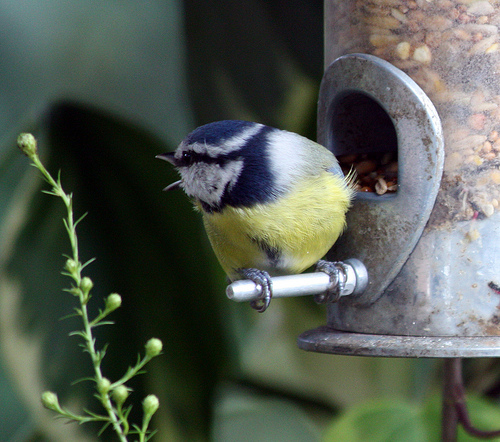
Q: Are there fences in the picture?
A: No, there are no fences.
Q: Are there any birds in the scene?
A: Yes, there is a bird.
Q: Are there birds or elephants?
A: Yes, there is a bird.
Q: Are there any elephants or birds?
A: Yes, there is a bird.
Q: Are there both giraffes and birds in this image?
A: No, there is a bird but no giraffes.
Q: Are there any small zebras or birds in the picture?
A: Yes, there is a small bird.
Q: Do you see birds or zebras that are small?
A: Yes, the bird is small.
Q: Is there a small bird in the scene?
A: Yes, there is a small bird.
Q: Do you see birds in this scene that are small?
A: Yes, there is a bird that is small.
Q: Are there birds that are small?
A: Yes, there is a bird that is small.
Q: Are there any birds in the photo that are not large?
A: Yes, there is a small bird.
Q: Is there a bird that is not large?
A: Yes, there is a small bird.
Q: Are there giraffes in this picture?
A: No, there are no giraffes.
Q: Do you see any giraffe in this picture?
A: No, there are no giraffes.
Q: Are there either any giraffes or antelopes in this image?
A: No, there are no giraffes or antelopes.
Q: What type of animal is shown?
A: The animal is a bird.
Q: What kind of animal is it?
A: The animal is a bird.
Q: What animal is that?
A: That is a bird.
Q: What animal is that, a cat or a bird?
A: That is a bird.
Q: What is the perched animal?
A: The animal is a bird.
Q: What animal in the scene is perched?
A: The animal is a bird.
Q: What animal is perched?
A: The animal is a bird.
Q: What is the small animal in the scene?
A: The animal is a bird.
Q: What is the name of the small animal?
A: The animal is a bird.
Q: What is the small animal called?
A: The animal is a bird.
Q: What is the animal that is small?
A: The animal is a bird.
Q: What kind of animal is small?
A: The animal is a bird.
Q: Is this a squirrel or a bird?
A: This is a bird.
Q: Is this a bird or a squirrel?
A: This is a bird.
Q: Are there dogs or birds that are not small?
A: No, there is a bird but it is small.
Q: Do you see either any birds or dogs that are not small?
A: No, there is a bird but it is small.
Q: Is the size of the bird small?
A: Yes, the bird is small.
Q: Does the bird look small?
A: Yes, the bird is small.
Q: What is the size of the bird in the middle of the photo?
A: The bird is small.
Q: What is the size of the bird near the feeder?
A: The bird is small.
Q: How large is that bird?
A: The bird is small.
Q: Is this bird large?
A: No, the bird is small.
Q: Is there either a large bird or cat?
A: No, there is a bird but it is small.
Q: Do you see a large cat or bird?
A: No, there is a bird but it is small.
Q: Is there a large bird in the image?
A: No, there is a bird but it is small.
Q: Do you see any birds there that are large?
A: No, there is a bird but it is small.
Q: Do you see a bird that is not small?
A: No, there is a bird but it is small.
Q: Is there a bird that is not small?
A: No, there is a bird but it is small.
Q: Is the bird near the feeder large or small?
A: The bird is small.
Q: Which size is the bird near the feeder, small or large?
A: The bird is small.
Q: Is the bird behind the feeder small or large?
A: The bird is small.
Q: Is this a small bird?
A: Yes, this is a small bird.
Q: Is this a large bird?
A: No, this is a small bird.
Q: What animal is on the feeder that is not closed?
A: The bird is on the feeder.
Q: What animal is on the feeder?
A: The animal is a bird.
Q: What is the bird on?
A: The bird is on the feeder.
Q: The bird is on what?
A: The bird is on the feeder.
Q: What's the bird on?
A: The bird is on the feeder.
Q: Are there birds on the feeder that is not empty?
A: Yes, there is a bird on the feeder.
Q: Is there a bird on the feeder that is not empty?
A: Yes, there is a bird on the feeder.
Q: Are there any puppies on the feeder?
A: No, there is a bird on the feeder.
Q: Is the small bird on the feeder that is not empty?
A: Yes, the bird is on the feeder.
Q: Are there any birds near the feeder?
A: Yes, there is a bird near the feeder.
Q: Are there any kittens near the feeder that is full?
A: No, there is a bird near the feeder.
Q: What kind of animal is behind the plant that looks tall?
A: The animal is a bird.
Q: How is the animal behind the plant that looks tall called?
A: The animal is a bird.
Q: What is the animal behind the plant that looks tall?
A: The animal is a bird.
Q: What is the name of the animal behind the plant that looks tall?
A: The animal is a bird.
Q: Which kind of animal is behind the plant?
A: The animal is a bird.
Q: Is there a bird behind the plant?
A: Yes, there is a bird behind the plant.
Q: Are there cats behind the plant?
A: No, there is a bird behind the plant.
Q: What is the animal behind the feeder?
A: The animal is a bird.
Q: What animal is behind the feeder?
A: The animal is a bird.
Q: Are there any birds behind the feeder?
A: Yes, there is a bird behind the feeder.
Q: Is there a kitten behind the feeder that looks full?
A: No, there is a bird behind the feeder.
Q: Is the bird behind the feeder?
A: Yes, the bird is behind the feeder.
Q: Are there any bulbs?
A: No, there are no bulbs.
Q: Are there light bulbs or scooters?
A: No, there are no light bulbs or scooters.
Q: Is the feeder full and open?
A: Yes, the feeder is full and open.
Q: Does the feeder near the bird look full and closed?
A: No, the feeder is full but open.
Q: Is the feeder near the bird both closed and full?
A: No, the feeder is full but open.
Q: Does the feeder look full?
A: Yes, the feeder is full.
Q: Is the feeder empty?
A: No, the feeder is full.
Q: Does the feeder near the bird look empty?
A: No, the feeder is full.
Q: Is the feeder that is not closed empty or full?
A: The feeder is full.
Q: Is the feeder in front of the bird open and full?
A: Yes, the feeder is open and full.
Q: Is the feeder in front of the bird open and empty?
A: No, the feeder is open but full.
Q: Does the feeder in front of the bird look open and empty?
A: No, the feeder is open but full.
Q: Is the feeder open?
A: Yes, the feeder is open.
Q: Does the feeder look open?
A: Yes, the feeder is open.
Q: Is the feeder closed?
A: No, the feeder is open.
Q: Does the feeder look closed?
A: No, the feeder is open.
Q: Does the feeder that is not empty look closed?
A: No, the feeder is open.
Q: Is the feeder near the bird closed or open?
A: The feeder is open.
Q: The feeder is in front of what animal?
A: The feeder is in front of the bird.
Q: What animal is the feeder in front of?
A: The feeder is in front of the bird.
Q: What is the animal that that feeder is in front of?
A: The animal is a bird.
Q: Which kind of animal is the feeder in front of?
A: The feeder is in front of the bird.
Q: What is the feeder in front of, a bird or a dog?
A: The feeder is in front of a bird.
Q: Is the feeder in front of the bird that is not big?
A: Yes, the feeder is in front of the bird.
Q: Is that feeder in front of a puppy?
A: No, the feeder is in front of the bird.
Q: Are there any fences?
A: No, there are no fences.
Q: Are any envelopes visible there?
A: No, there are no envelopes.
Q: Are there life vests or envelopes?
A: No, there are no envelopes or life vests.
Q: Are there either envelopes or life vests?
A: No, there are no envelopes or life vests.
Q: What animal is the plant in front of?
A: The plant is in front of the bird.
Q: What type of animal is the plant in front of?
A: The plant is in front of the bird.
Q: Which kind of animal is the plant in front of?
A: The plant is in front of the bird.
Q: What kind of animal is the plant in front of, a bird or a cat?
A: The plant is in front of a bird.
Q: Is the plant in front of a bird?
A: Yes, the plant is in front of a bird.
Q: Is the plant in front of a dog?
A: No, the plant is in front of a bird.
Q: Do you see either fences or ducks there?
A: No, there are no fences or ducks.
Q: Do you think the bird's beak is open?
A: Yes, the beak is open.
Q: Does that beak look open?
A: Yes, the beak is open.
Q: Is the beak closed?
A: No, the beak is open.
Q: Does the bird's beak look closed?
A: No, the beak is open.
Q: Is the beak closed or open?
A: The beak is open.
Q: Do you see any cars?
A: No, there are no cars.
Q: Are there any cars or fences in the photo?
A: No, there are no cars or fences.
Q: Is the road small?
A: Yes, the road is small.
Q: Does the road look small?
A: Yes, the road is small.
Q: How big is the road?
A: The road is small.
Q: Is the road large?
A: No, the road is small.